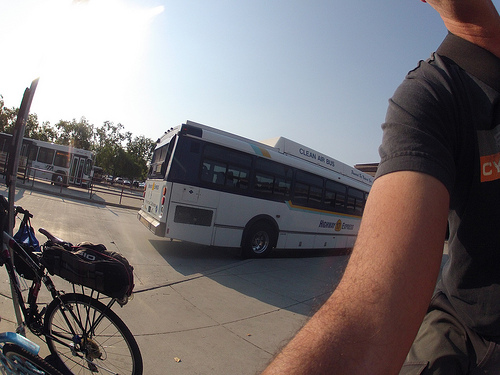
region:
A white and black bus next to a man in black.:
[136, 117, 375, 254]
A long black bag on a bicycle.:
[43, 234, 133, 304]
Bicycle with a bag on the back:
[1, 199, 143, 374]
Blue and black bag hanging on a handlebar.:
[12, 210, 44, 275]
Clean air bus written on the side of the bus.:
[297, 148, 335, 167]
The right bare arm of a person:
[263, 172, 449, 374]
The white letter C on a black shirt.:
[481, 158, 494, 178]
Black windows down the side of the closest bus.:
[201, 142, 370, 212]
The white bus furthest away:
[0, 129, 96, 191]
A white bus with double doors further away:
[2, 129, 97, 191]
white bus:
[159, 106, 343, 254]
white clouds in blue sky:
[15, 19, 67, 53]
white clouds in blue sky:
[55, 12, 115, 62]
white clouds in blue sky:
[66, 65, 111, 102]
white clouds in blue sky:
[116, 15, 197, 57]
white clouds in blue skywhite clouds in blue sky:
[111, 75, 168, 107]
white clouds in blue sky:
[168, 20, 248, 80]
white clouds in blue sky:
[213, 43, 290, 108]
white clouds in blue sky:
[322, 23, 376, 80]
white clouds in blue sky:
[271, 79, 343, 129]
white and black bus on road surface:
[123, 116, 373, 264]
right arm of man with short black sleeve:
[264, 62, 456, 366]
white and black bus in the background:
[3, 118, 110, 215]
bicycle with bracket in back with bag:
[2, 190, 161, 369]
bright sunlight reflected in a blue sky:
[57, 0, 253, 119]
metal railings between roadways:
[76, 167, 157, 210]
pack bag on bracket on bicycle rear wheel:
[27, 219, 137, 309]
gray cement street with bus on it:
[52, 225, 293, 365]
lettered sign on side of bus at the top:
[272, 138, 355, 175]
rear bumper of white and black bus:
[130, 198, 173, 248]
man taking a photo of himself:
[162, 6, 499, 369]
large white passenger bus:
[134, 128, 397, 253]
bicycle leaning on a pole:
[0, 206, 157, 357]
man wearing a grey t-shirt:
[394, 34, 496, 313]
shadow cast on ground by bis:
[216, 227, 356, 317]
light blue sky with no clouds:
[263, 44, 329, 102]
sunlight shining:
[3, 0, 148, 116]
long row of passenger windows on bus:
[197, 143, 394, 219]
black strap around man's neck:
[425, 23, 498, 100]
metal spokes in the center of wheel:
[35, 291, 156, 371]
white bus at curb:
[127, 110, 352, 255]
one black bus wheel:
[238, 211, 281, 258]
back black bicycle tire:
[34, 290, 159, 374]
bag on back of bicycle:
[35, 225, 139, 306]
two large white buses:
[6, 88, 359, 258]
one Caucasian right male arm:
[246, 168, 458, 373]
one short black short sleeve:
[363, 61, 460, 211]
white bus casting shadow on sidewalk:
[135, 116, 330, 321]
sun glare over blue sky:
[4, 8, 256, 114]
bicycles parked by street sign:
[4, 75, 160, 373]